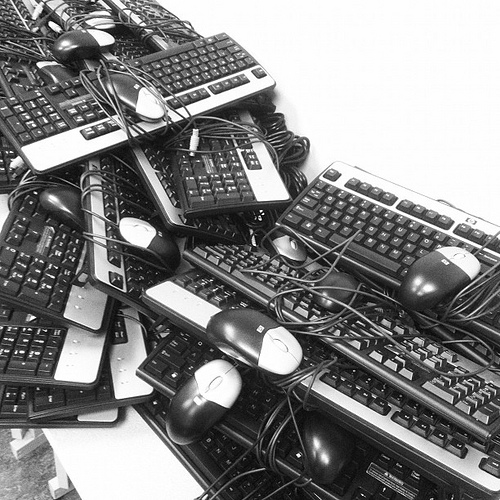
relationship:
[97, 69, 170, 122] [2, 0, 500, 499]
computer mouse in a pile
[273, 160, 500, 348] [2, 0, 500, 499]
computer keyboard in a pile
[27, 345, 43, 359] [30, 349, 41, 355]
black keys with white letters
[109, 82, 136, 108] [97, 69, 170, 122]
lights shinning on computer mouse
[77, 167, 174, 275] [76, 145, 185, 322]
wires are covering computer keyboard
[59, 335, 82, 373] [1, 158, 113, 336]
three lights on a keyboard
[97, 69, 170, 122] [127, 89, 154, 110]
computer mouse that white and grey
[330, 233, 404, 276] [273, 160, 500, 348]
black space key on keyboard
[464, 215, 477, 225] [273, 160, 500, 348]
hp logo on keyboard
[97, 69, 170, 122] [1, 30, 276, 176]
computer mouse resting on top of a keyboard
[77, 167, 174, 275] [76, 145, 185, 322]
tangled mess of wire on top of keyboard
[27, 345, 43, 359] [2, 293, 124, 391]
keys on keyboard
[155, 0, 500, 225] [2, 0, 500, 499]
white wall behind stacks of keyboards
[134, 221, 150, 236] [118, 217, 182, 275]
scrolling button in middle of computer mouse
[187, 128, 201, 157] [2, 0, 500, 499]
plug for electronics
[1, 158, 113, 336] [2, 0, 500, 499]
keyboard in a pile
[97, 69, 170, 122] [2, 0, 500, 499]
mouse in a pile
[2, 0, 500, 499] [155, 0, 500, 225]
table up against wall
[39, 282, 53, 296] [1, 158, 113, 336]
buttons on a keyboard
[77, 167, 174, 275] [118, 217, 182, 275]
wires to mouse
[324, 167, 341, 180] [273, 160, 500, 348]
escape button on a keyboard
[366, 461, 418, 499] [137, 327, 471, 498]
warning sticker on a keyboard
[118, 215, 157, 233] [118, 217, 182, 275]
button on a mouse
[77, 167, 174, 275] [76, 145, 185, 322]
wires wrapped behind keyboard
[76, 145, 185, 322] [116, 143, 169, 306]
computer keyboard that black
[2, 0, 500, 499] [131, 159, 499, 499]
large stack of keyboards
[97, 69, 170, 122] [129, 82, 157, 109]
computer mouse that black and white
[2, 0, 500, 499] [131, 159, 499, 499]
whole bunch of keyboards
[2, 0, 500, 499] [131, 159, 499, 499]
bunch of keyboards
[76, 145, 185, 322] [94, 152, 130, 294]
keyboard that black and white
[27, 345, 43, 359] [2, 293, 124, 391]
black keys on a keyboard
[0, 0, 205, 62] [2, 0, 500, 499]
black wires on top of keyboards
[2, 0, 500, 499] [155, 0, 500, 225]
keyboards on top of a white table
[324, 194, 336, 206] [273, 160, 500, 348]
letter q on a keyboard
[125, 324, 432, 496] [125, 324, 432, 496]
keyboard piled on top of keyboard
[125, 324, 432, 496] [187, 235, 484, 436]
keyboard piled on top of keyboard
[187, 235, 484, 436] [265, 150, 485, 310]
keyboard piled on top of keyboard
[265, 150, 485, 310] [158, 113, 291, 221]
keyboard piled on top of keyboard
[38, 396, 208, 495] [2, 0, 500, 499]
table has keyboards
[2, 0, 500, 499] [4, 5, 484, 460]
table has keyboards